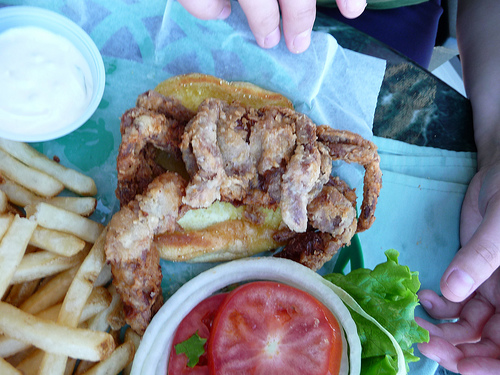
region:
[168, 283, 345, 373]
Two tomato slices on top of lettuce.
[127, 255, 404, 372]
White onion around two slices of tomatoes.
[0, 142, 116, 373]
French fries beside onion and tomatoes.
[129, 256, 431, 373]
Onion, tomatoes and lettuce taken of the sandwich.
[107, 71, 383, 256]
Meat on the bottom of a bun.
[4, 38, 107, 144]
Condiment in a cup to put on sandwich.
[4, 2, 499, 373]
Person getting to eat a sandwich with french fries.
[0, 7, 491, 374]
Sandwich with fries on the table.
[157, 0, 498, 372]
The hands of a man on the table.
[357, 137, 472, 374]
White napkin under the person's hand on the table.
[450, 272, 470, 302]
part of a nail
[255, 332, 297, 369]
part of a tomato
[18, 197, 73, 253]
portion of some chips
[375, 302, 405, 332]
part of some spinach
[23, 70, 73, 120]
portion of some white cream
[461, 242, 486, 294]
part of a thumb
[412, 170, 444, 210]
part of a cloth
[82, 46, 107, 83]
edge of a dish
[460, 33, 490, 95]
part of an arm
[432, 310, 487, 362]
fingers of the left hand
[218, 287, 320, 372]
a slice of tomatoe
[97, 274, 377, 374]
three slices of onion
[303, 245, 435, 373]
green leaf lettuce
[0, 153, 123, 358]
several french fried potatoes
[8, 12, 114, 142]
small cup of sauce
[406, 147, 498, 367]
a person's hand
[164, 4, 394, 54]
a person's fingers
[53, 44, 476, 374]
a tray of food on a table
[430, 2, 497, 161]
a person's arm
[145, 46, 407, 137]
a white piece of paper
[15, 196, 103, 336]
French fries next to a sandwich.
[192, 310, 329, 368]
There are two tomatoes.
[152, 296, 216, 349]
There are three onions.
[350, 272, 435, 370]
There is a leaf of lettuce.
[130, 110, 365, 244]
Chicken on a bun.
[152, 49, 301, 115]
Bun on a wrapper.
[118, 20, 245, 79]
The wrapper is blue.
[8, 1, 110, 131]
Mayo in a cup.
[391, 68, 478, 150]
The table is green marble.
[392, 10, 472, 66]
The person is wearing blue pants.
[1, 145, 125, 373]
Pile of fries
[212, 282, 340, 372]
Sliced red tomatoes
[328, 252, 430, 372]
part of a lettuce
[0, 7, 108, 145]
Glass of water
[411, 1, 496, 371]
Left arm of the individual eating the food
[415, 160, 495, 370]
Left hand of the individual eating the food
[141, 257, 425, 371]
The white onions are on top of the sandwich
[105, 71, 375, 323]
Sandwich with white meat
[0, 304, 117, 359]
One fry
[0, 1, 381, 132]
Light sky blue paper used to hold the food